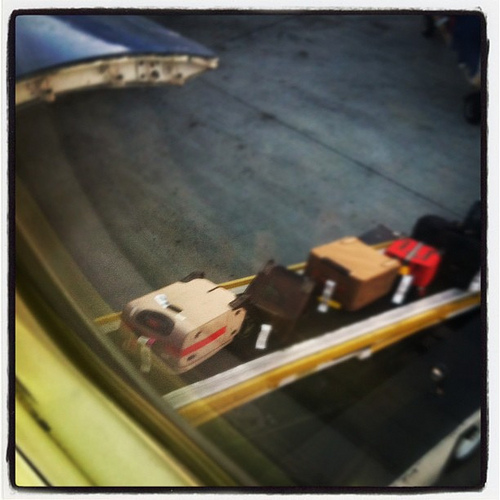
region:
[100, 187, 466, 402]
suitcases on a conveyer belt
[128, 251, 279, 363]
the suitcase is at the top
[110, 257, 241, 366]
the suitcase has a red line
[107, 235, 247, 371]
the suitcase is beige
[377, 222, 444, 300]
the bag is red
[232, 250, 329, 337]
the bag is brown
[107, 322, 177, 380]
a white tag on the handle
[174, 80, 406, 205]
the ground is grey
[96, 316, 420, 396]
the conveyer belt is black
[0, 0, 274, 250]
the door is up and open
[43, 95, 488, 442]
Luggage on an escalator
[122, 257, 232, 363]
A tan colored suitcase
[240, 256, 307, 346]
A black suitcase next to beige suitcase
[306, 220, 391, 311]
A brown colored suitcase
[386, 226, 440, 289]
A red suitcase next to brown suitcase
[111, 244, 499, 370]
An escalator for luggage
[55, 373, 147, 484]
A piece of yellow metal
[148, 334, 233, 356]
A bright orange stripe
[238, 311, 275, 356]
Tag marking luggage at an airport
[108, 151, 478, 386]
Conveyor belt of luggage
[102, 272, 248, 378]
Tan and red luggage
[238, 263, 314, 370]
Solid black luggage with white tag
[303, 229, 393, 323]
Huge solid brown luggage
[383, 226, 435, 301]
Red and silver luggage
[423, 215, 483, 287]
Big solid black luggage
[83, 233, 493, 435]
White, yellow and black conveyor belt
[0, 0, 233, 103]
Raised blue door of airplane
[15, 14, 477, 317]
Air field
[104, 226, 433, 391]
White labeling tags on luggage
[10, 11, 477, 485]
view from inside an airplane looking out the window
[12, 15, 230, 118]
blue door of the cargo area of an airplane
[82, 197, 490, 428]
black, yellow and silver luggage conveyor belt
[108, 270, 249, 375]
tan suitcase with red trim and destination tag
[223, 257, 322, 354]
black wheeled suitcase with destination tag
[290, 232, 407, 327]
tan wheeled suitcase with destination tag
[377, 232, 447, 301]
red suitcase with white destination tag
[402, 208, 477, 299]
black nondescript luggage on conveyor belt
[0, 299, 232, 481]
part of an airplane window frame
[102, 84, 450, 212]
gray pavement of an airport tarmac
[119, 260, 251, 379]
Tan luggage on the conveyor.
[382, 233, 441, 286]
Red luggage on the conveyor.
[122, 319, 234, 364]
Red stripe on the luggage.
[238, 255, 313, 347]
Black luggage on the conveyor.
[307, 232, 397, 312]
Brown luggage on the conveyor.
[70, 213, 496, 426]
Conveyor belt loading luggage.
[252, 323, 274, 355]
White tag on the luggage.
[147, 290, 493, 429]
Yellow stripe on the conveyor.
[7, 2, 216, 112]
Door on the plane.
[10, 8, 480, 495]
Window on the airplane.